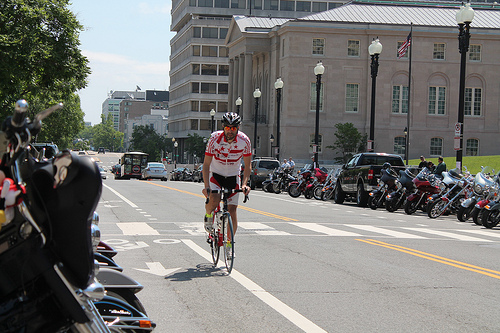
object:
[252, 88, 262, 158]
street lights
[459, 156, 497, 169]
grass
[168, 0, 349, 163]
building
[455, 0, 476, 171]
light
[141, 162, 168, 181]
car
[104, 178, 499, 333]
line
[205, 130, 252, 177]
shirt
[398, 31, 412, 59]
flag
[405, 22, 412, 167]
pole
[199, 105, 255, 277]
skateboarder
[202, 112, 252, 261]
rider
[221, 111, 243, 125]
helmet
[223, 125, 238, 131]
sunglasses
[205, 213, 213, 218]
sock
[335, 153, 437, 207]
truck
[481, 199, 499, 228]
motorcycle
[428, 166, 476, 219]
motorcycles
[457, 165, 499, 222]
motorcycles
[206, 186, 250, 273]
bike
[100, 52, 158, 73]
train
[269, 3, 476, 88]
globes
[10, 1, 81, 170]
trees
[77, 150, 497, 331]
street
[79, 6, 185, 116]
weather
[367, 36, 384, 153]
lights